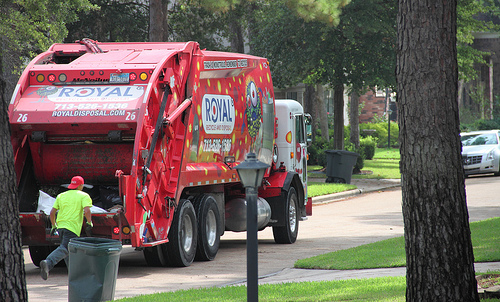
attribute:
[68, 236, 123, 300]
garbage can — empty 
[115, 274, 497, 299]
grass — green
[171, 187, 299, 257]
wheels — large 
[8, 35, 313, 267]
trash truck — red, decorated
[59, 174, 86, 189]
hat — red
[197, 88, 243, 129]
word — blue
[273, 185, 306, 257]
tire — black 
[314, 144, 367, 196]
trash can — green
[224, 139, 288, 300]
lamp — black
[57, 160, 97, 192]
hat — backwards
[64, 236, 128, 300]
can — garbage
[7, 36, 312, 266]
garbage truck — red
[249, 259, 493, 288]
driveway — paved 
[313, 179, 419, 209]
corner — street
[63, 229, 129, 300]
can — trash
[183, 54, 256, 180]
dots — polka